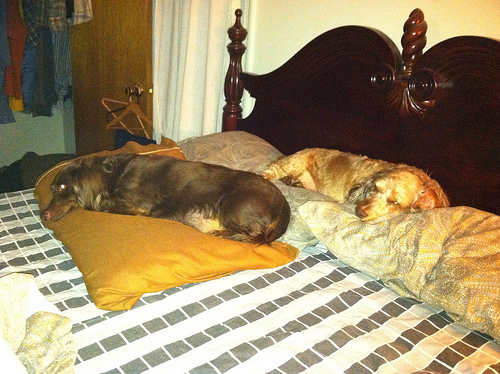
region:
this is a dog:
[51, 136, 306, 236]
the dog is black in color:
[152, 153, 192, 192]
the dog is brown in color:
[326, 150, 346, 175]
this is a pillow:
[77, 217, 160, 282]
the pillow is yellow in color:
[128, 225, 175, 259]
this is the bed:
[295, 42, 436, 96]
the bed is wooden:
[336, 67, 408, 151]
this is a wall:
[258, 6, 297, 45]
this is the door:
[78, 27, 150, 85]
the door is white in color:
[259, 16, 292, 49]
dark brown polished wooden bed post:
[225, 5, 245, 125]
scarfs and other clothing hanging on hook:
[18, 1, 75, 120]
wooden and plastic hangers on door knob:
[98, 85, 155, 137]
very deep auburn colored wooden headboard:
[248, 18, 498, 201]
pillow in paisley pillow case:
[328, 204, 498, 338]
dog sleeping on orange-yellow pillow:
[31, 130, 293, 282]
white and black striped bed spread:
[111, 309, 477, 371]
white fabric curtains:
[154, 1, 249, 142]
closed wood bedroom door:
[72, 1, 152, 155]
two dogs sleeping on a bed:
[36, 132, 447, 245]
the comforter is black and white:
[198, 283, 399, 362]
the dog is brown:
[270, 147, 438, 230]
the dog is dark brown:
[56, 138, 294, 250]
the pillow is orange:
[63, 221, 246, 309]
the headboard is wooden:
[227, 22, 489, 169]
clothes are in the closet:
[6, 19, 76, 115]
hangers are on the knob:
[108, 87, 164, 137]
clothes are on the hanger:
[111, 125, 161, 145]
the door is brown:
[70, 18, 159, 151]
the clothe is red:
[6, 15, 24, 100]